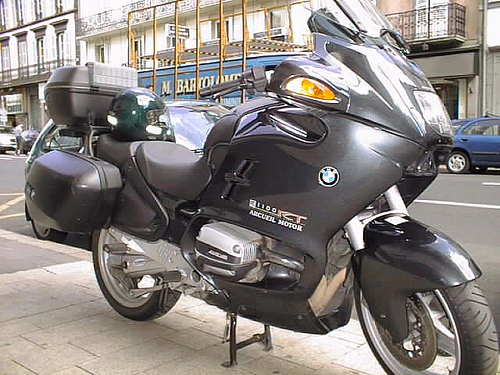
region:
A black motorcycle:
[47, 48, 436, 352]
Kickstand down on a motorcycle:
[201, 286, 294, 364]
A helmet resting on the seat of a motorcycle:
[96, 75, 186, 155]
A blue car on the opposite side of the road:
[437, 105, 497, 157]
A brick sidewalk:
[27, 301, 119, 366]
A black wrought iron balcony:
[378, 3, 473, 51]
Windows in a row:
[10, 14, 81, 79]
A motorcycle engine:
[169, 203, 289, 288]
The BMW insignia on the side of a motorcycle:
[309, 155, 363, 204]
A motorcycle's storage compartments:
[38, 55, 143, 251]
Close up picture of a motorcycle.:
[22, 2, 496, 357]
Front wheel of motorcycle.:
[345, 209, 497, 373]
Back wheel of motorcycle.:
[81, 225, 182, 324]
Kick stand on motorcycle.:
[212, 308, 295, 370]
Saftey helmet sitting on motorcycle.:
[101, 67, 181, 149]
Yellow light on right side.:
[282, 62, 354, 112]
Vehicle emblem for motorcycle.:
[313, 152, 345, 194]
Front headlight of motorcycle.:
[400, 75, 461, 151]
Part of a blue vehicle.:
[445, 100, 499, 175]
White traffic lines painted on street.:
[438, 180, 498, 220]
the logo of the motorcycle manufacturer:
[308, 163, 370, 196]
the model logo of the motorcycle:
[228, 188, 318, 245]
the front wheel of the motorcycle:
[348, 203, 495, 373]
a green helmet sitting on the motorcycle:
[88, 78, 199, 164]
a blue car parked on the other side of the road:
[453, 84, 498, 175]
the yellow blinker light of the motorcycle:
[256, 64, 364, 122]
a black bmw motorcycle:
[26, 13, 495, 356]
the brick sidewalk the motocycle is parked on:
[29, 293, 359, 373]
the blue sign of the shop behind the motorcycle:
[139, 51, 285, 106]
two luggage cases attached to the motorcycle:
[16, 44, 136, 244]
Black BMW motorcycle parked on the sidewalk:
[22, 0, 498, 373]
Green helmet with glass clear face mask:
[0, 225, 29, 227]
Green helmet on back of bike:
[101, 87, 177, 142]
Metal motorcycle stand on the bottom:
[219, 307, 274, 369]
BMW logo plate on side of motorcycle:
[312, 163, 344, 188]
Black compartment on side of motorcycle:
[21, 150, 121, 232]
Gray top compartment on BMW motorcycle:
[44, 60, 136, 125]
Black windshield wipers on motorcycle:
[300, 0, 411, 47]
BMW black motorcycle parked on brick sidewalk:
[10, 2, 498, 373]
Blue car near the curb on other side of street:
[446, 115, 498, 175]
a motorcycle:
[43, 3, 496, 366]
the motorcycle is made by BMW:
[22, 7, 499, 371]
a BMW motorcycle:
[18, 6, 498, 373]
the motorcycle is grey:
[27, 6, 499, 368]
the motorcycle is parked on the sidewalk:
[18, 13, 488, 373]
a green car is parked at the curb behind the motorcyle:
[18, 18, 497, 371]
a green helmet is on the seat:
[97, 80, 181, 159]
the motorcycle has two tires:
[43, 23, 486, 373]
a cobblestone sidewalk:
[16, 249, 476, 373]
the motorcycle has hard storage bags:
[20, 16, 162, 294]